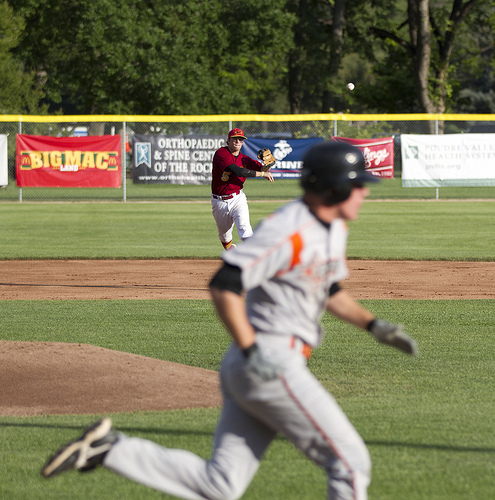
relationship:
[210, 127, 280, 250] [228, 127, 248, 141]
player wearing cap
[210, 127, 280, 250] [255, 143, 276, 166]
player wearing glove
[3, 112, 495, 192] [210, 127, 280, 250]
barrier behind player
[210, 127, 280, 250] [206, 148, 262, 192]
player wearing shirt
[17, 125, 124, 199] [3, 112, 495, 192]
ad on barrier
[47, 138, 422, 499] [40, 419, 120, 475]
player wearing sneaker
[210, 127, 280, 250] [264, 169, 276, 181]
player has hand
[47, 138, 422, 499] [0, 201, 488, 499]
player running on field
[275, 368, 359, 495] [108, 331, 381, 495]
pinstripe on pants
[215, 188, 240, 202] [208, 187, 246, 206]
belt around waist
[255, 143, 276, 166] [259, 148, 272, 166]
glove in hand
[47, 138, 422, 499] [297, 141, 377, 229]
player has head